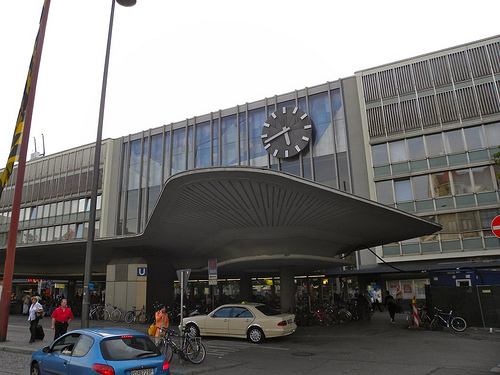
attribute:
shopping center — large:
[18, 31, 493, 323]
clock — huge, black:
[252, 104, 342, 180]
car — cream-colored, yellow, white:
[189, 292, 282, 341]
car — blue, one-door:
[44, 322, 179, 375]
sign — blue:
[130, 267, 156, 284]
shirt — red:
[48, 303, 86, 326]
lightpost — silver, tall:
[90, 9, 130, 345]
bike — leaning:
[419, 307, 465, 336]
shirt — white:
[23, 303, 44, 329]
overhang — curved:
[143, 163, 449, 266]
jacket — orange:
[156, 306, 173, 336]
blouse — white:
[31, 301, 49, 323]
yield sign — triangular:
[175, 270, 194, 288]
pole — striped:
[408, 305, 425, 328]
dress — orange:
[147, 306, 174, 340]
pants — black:
[48, 321, 70, 349]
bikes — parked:
[407, 300, 470, 336]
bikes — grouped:
[83, 295, 175, 328]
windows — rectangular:
[120, 140, 358, 226]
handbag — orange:
[142, 314, 155, 345]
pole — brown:
[3, 13, 55, 281]